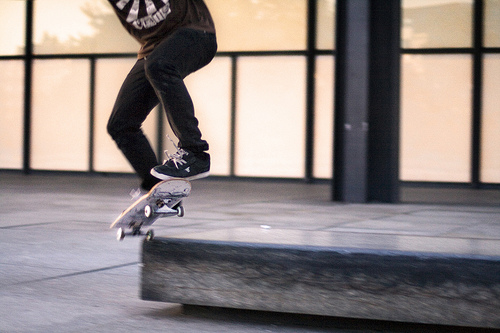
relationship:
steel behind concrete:
[343, 0, 398, 205] [148, 202, 478, 325]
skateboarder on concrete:
[109, 0, 238, 253] [129, 200, 471, 317]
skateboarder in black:
[109, 0, 238, 253] [111, 30, 213, 165]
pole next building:
[343, 0, 398, 205] [0, 1, 480, 162]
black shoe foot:
[111, 30, 213, 165] [148, 144, 209, 186]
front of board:
[151, 176, 192, 202] [107, 172, 191, 238]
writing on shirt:
[101, 0, 180, 27] [96, 0, 214, 48]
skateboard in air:
[107, 172, 191, 238] [72, 99, 244, 273]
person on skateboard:
[109, 0, 238, 253] [107, 172, 191, 238]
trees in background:
[32, 11, 107, 55] [0, 1, 480, 162]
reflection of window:
[371, 3, 483, 232] [387, 6, 494, 180]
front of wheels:
[151, 176, 192, 202] [116, 200, 185, 249]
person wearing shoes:
[131, 0, 207, 212] [148, 144, 209, 186]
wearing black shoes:
[109, 146, 218, 205] [148, 144, 209, 186]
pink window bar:
[387, 6, 494, 180] [464, 26, 486, 191]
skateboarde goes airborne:
[107, 172, 191, 238] [109, 0, 238, 253]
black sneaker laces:
[111, 30, 213, 165] [164, 137, 190, 171]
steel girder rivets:
[311, 12, 409, 198] [327, 115, 371, 142]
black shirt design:
[111, 30, 213, 165] [96, 0, 214, 48]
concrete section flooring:
[392, 200, 485, 232] [0, 172, 112, 331]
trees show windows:
[32, 11, 107, 55] [0, 3, 77, 172]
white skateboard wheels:
[178, 204, 189, 221] [116, 200, 185, 249]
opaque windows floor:
[0, 3, 77, 172] [0, 172, 112, 331]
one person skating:
[109, 0, 238, 253] [97, 142, 213, 258]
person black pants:
[131, 0, 207, 212] [111, 30, 213, 165]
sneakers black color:
[109, 146, 218, 205] [148, 144, 209, 186]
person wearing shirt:
[131, 0, 207, 212] [96, 0, 214, 48]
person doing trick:
[131, 0, 207, 212] [38, 1, 231, 286]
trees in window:
[32, 11, 107, 55] [0, 3, 77, 172]